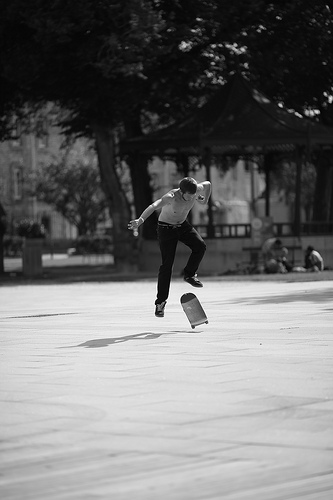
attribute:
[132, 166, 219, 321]
man — skating, small, white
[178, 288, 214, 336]
board — black, long, close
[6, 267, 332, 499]
ground — silver, gray, grey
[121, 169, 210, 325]
man — shirtless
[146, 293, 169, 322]
shoe — skateboard, single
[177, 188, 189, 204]
beard — man's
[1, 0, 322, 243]
trees — tall, wide, green, big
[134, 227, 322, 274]
wall — long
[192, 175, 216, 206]
arm — bent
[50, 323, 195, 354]
shadow — skater's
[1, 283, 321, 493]
ground — wide, paved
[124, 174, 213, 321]
guy — shirtless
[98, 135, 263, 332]
person — shadow